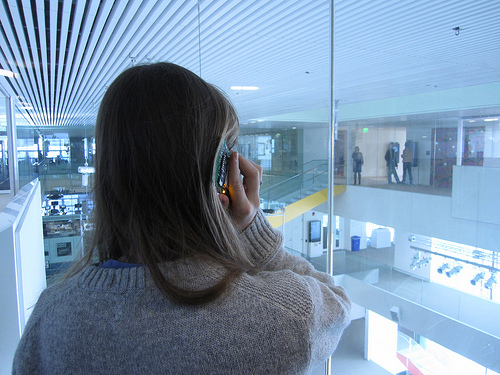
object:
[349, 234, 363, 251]
can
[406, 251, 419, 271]
light fixture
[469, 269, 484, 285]
light fixture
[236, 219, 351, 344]
arm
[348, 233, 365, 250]
bin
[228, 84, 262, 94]
light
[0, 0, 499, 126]
ceiling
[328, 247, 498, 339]
window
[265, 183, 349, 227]
yellow trim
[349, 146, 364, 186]
woman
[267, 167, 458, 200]
hallway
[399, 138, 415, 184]
people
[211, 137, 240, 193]
phone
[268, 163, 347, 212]
arm rail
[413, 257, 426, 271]
light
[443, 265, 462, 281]
light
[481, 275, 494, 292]
light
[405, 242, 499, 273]
bar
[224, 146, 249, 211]
finger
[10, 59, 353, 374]
person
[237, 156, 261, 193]
finger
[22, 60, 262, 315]
hair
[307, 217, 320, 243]
sign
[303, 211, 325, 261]
wall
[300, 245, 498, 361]
hallway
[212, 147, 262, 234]
hand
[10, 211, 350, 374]
grey sweater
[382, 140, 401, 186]
person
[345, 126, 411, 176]
wall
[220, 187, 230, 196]
light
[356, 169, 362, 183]
legs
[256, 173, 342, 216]
stairs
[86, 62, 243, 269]
head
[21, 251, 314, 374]
back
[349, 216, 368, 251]
wall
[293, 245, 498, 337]
floor